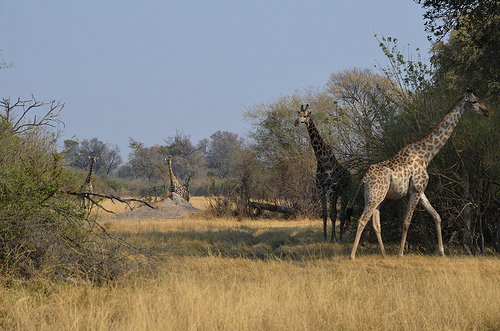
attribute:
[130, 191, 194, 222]
anthill — ant, grey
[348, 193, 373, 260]
legs — long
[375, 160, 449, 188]
polygons — brown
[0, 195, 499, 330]
grass — brown, long, dead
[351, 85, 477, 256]
giraffe — walking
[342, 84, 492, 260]
animal —  in africa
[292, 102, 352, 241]
animal —  in africa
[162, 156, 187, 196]
animal —  in africa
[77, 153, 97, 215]
animal —  in africa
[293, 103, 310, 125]
head —  giraffe's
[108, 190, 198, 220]
rock — large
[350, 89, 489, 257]
giraffe —  four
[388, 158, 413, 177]
spots — brown, white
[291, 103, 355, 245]
giraffe — walking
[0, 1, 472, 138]
sky —  without clouds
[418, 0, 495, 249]
mountain — large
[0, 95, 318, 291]
trees —  Multiple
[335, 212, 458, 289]
hooves —   two 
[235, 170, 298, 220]
tree — dead, fallen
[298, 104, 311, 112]
horns — short, knobbed